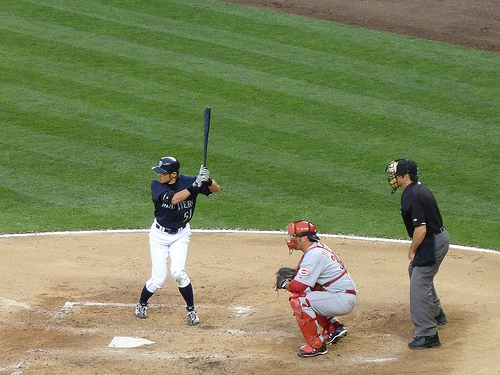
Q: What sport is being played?
A: Baseball.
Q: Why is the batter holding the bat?
A: Waiting for the ball.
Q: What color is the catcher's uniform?
A: Red and gray.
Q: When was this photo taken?
A: During the daytime.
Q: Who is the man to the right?
A: The umpire.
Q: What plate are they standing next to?
A: Home plate.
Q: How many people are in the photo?
A: Three.